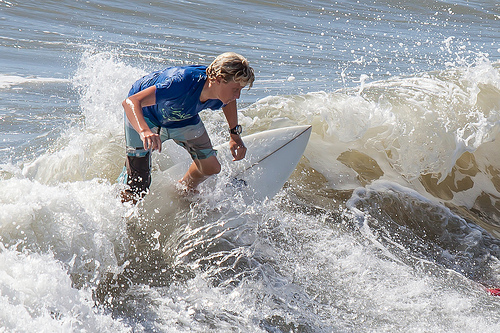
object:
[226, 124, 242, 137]
watch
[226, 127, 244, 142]
wrist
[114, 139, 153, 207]
leg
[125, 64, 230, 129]
shirt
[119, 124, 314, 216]
surfboard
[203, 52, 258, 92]
hair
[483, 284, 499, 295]
object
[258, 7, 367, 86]
water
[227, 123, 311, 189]
line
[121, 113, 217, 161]
shortsa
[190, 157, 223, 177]
knee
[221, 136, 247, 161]
hand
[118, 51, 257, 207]
man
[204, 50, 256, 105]
head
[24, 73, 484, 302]
waves